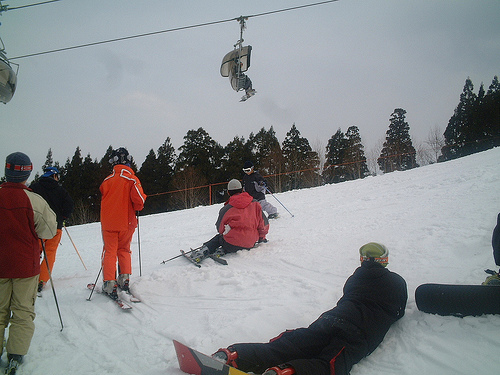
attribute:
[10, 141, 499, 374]
snow — white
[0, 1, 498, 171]
sky — stormy looking, grey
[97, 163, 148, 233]
jacket — orange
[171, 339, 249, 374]
snowboard — red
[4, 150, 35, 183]
cap — gray, orange, grey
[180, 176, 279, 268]
skier — sitting, sitting in snow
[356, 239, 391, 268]
hat — green, orange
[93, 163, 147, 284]
skisuit — orange, white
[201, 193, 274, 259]
skisuit — red, black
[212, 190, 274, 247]
jacket — red, black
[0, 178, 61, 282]
jacket — red, tan, maroon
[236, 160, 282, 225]
skier — skiing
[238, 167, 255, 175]
goggles — white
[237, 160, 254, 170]
hat — black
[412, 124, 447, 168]
trees — bare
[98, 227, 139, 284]
pants — orange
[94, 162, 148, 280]
snowsuit — orange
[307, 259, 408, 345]
jacket — black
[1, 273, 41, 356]
pants — tan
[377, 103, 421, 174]
tree — green